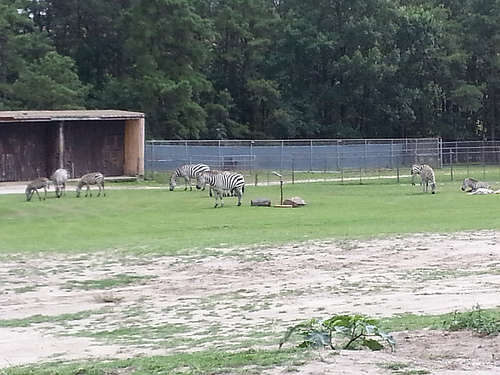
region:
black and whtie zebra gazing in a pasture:
[195, 168, 254, 208]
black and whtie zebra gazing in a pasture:
[403, 159, 446, 201]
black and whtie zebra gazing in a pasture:
[161, 150, 201, 194]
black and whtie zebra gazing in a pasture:
[73, 170, 112, 202]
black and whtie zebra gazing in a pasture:
[48, 163, 73, 203]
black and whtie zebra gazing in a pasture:
[14, 175, 54, 210]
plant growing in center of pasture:
[275, 303, 397, 373]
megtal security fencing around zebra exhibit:
[154, 123, 498, 188]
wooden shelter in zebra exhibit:
[0, 99, 157, 184]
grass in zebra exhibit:
[48, 198, 410, 293]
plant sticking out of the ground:
[286, 310, 397, 360]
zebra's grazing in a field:
[22, 146, 498, 208]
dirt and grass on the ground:
[0, 222, 497, 374]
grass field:
[2, 170, 499, 256]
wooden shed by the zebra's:
[0, 105, 147, 192]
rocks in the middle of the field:
[252, 165, 305, 214]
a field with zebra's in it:
[2, 150, 498, 372]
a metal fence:
[141, 130, 498, 188]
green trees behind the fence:
[2, 1, 497, 145]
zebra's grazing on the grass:
[18, 156, 448, 209]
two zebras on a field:
[158, 155, 248, 221]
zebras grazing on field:
[164, 163, 245, 205]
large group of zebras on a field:
[22, 154, 484, 246]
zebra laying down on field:
[454, 182, 495, 199]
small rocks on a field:
[248, 189, 320, 218]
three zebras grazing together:
[22, 168, 112, 213]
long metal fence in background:
[142, 135, 443, 180]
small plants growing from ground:
[271, 308, 407, 368]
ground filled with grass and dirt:
[117, 231, 382, 348]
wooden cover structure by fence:
[0, 108, 150, 174]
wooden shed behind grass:
[1, 105, 147, 182]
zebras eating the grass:
[24, 165, 452, 205]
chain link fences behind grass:
[151, 140, 499, 187]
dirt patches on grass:
[3, 226, 498, 358]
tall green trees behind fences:
[0, 1, 498, 154]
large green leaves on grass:
[277, 308, 394, 358]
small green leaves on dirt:
[438, 305, 498, 340]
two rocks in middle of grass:
[253, 194, 308, 213]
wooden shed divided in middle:
[0, 109, 148, 195]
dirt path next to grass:
[1, 170, 438, 191]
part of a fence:
[331, 140, 341, 160]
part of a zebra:
[233, 180, 236, 186]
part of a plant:
[353, 327, 367, 336]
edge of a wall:
[142, 145, 149, 165]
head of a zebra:
[185, 164, 207, 192]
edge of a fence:
[383, 150, 390, 153]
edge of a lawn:
[213, 269, 225, 281]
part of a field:
[426, 313, 458, 330]